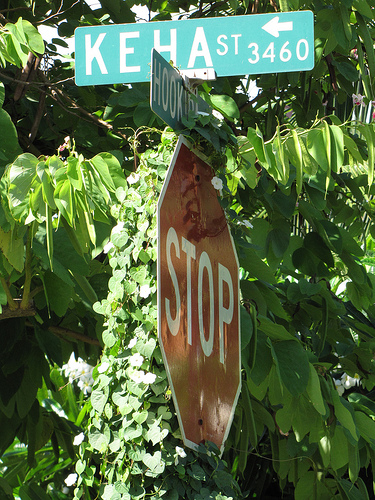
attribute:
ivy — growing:
[75, 129, 223, 500]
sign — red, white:
[156, 133, 243, 459]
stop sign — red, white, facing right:
[153, 133, 243, 461]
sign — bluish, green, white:
[72, 9, 317, 89]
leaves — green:
[77, 130, 157, 493]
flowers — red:
[351, 90, 375, 126]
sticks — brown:
[20, 67, 111, 144]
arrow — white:
[260, 13, 295, 38]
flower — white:
[212, 175, 226, 192]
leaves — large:
[9, 146, 126, 308]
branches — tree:
[9, 54, 136, 161]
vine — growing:
[67, 129, 196, 499]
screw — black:
[198, 414, 206, 428]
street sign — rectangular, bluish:
[147, 50, 228, 172]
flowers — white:
[61, 351, 96, 396]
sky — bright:
[11, 1, 375, 105]